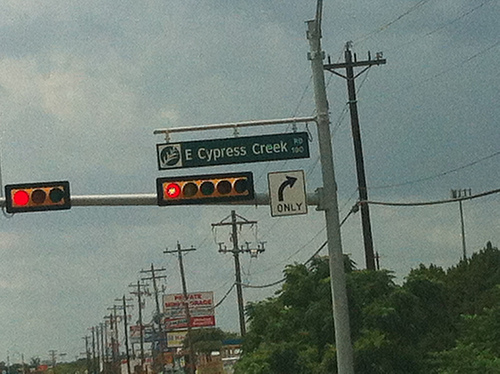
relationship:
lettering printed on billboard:
[162, 292, 211, 305] [161, 290, 217, 329]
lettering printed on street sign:
[182, 135, 305, 161] [155, 129, 311, 171]